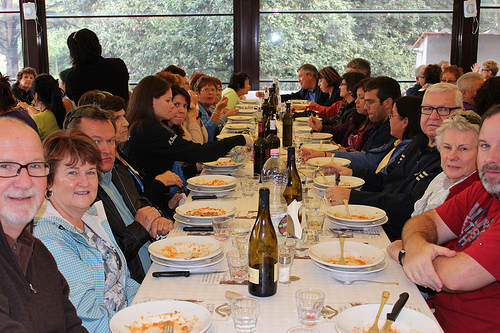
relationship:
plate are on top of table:
[146, 235, 225, 271] [221, 82, 426, 328]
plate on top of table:
[146, 235, 225, 271] [106, 91, 439, 331]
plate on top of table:
[301, 238, 388, 273] [106, 91, 439, 331]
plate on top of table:
[106, 300, 214, 333] [106, 91, 439, 331]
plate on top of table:
[332, 304, 441, 333] [106, 91, 439, 331]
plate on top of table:
[181, 170, 240, 196] [106, 91, 439, 331]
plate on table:
[106, 300, 214, 333] [106, 91, 439, 331]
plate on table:
[332, 296, 439, 330] [106, 91, 439, 331]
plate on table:
[111, 296, 219, 330] [106, 91, 439, 331]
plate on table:
[142, 234, 223, 264] [106, 91, 439, 331]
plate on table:
[307, 238, 390, 283] [106, 91, 439, 331]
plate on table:
[326, 204, 386, 230] [106, 91, 439, 331]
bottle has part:
[246, 184, 280, 299] [259, 287, 269, 293]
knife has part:
[381, 290, 408, 330] [384, 312, 396, 321]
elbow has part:
[433, 276, 475, 297] [444, 254, 469, 279]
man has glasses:
[3, 118, 72, 330] [4, 161, 54, 182]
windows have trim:
[43, 10, 456, 83] [237, 6, 263, 82]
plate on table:
[332, 304, 441, 333] [106, 91, 439, 331]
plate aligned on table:
[332, 304, 441, 333] [115, 67, 445, 332]